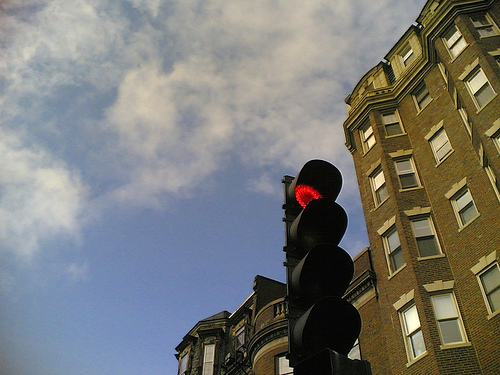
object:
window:
[457, 201, 480, 225]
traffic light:
[279, 158, 362, 368]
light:
[295, 185, 324, 209]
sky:
[0, 0, 429, 375]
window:
[435, 141, 453, 163]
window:
[473, 82, 497, 111]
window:
[385, 122, 406, 138]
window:
[415, 234, 443, 260]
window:
[437, 317, 468, 346]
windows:
[476, 25, 500, 37]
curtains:
[432, 295, 457, 320]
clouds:
[0, 0, 424, 308]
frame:
[437, 316, 466, 348]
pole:
[290, 348, 372, 375]